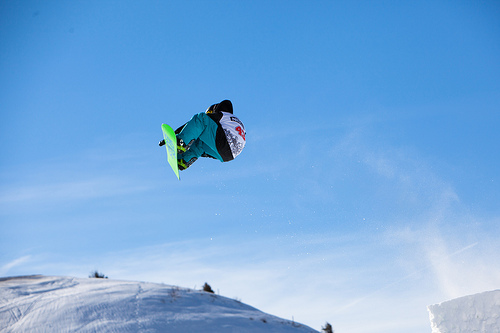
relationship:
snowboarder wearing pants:
[162, 99, 246, 179] [174, 111, 226, 168]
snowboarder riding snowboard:
[162, 99, 246, 179] [158, 125, 184, 178]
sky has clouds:
[1, 1, 499, 302] [411, 227, 468, 282]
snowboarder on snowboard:
[162, 99, 246, 179] [158, 125, 184, 178]